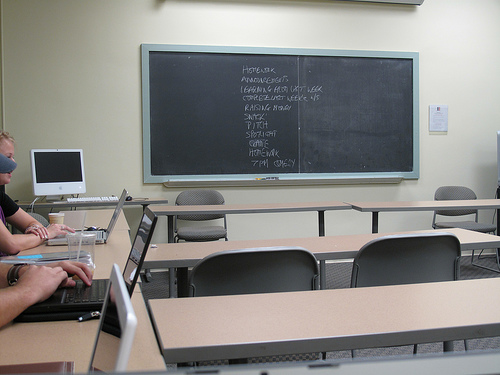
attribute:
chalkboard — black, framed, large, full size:
[147, 47, 424, 191]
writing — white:
[241, 66, 304, 157]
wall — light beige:
[14, 7, 499, 188]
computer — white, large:
[28, 146, 118, 211]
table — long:
[146, 194, 497, 239]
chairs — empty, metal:
[177, 241, 489, 291]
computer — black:
[36, 206, 154, 312]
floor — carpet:
[142, 267, 366, 299]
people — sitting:
[4, 140, 87, 343]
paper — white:
[431, 103, 453, 135]